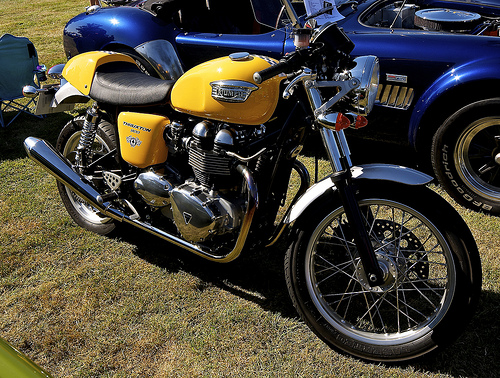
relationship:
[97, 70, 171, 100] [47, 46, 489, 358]
seat on motorcycle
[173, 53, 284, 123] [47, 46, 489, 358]
tank on bike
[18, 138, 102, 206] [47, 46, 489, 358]
pipe on motorcycle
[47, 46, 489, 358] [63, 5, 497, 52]
motorcycle next to car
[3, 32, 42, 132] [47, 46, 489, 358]
chair behind motorcycle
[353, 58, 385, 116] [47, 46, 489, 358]
headlight of motorcycle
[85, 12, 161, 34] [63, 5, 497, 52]
blue on car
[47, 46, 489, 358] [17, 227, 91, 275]
motorcycle on grass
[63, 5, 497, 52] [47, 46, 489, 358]
sportscar behind motorcycle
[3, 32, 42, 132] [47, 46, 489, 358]
chair behind vehicles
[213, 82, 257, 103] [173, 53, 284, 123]
panel on cover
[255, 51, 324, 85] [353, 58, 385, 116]
handlebars over headlight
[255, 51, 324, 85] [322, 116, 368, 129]
handlebars over turnsignals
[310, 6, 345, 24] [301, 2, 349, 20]
paper under wiper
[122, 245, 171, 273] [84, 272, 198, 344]
shadow on ground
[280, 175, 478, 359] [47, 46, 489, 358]
tire on motorcycle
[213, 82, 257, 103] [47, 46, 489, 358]
logo on motorcycle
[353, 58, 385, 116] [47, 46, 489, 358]
headlight on motorcycle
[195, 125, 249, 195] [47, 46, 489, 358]
engine on motorcycle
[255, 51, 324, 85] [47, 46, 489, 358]
handlebars on motorcycle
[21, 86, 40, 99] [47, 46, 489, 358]
light on motorcycle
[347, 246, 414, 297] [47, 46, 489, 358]
brake on motorcycle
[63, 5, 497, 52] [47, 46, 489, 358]
car behind motorcycle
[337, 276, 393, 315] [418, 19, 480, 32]
spokes on wheel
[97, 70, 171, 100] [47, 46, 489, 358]
seat of motorcycle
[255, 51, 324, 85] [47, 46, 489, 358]
handlebars of motorcycle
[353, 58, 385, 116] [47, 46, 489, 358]
headlamp on motorcycle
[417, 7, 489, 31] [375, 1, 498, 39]
filter on car engine